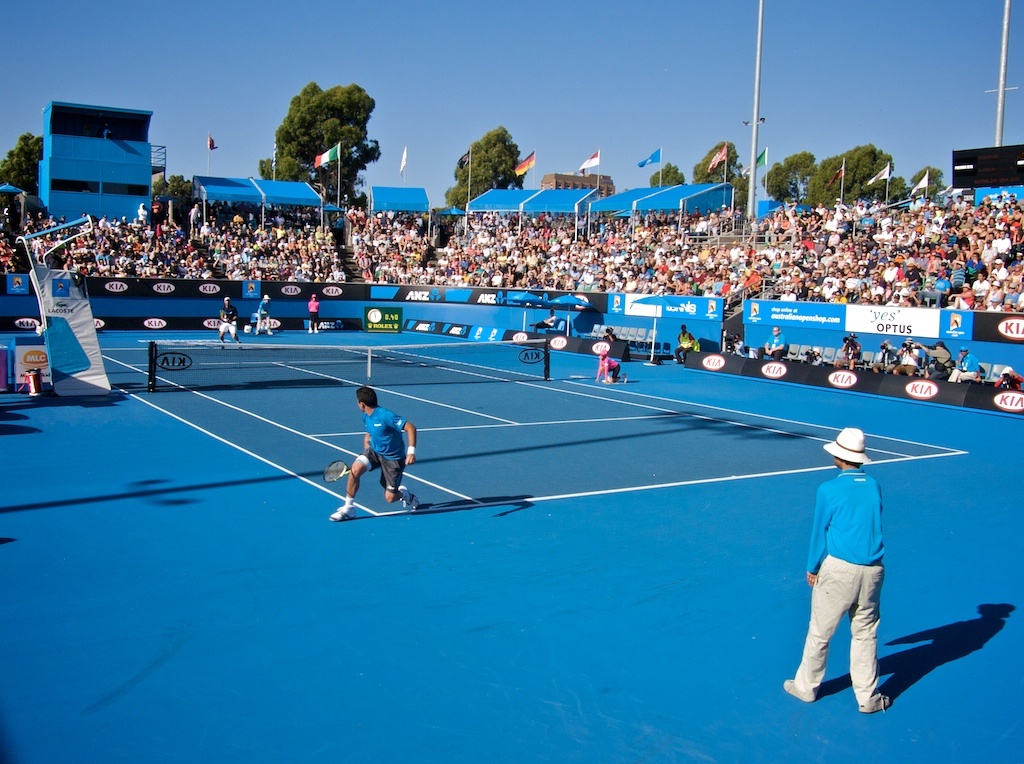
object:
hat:
[822, 428, 871, 463]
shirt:
[807, 469, 885, 575]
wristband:
[407, 445, 415, 454]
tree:
[258, 81, 381, 211]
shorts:
[357, 445, 406, 491]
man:
[783, 427, 890, 714]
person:
[323, 386, 419, 522]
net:
[148, 339, 550, 393]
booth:
[16, 213, 112, 396]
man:
[219, 296, 240, 350]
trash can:
[18, 367, 43, 396]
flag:
[515, 150, 536, 177]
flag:
[637, 148, 662, 168]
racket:
[323, 460, 352, 483]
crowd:
[0, 194, 1024, 313]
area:
[38, 100, 153, 227]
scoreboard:
[953, 144, 1024, 187]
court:
[0, 329, 1024, 764]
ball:
[244, 325, 252, 334]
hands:
[345, 468, 352, 474]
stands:
[0, 182, 1024, 377]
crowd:
[0, 194, 1024, 391]